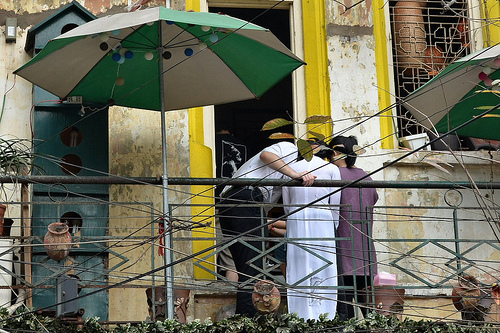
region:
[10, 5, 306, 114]
the green and white umbrella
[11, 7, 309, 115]
the umbrella is green and white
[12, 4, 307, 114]
the opened umbrella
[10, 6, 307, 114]
the umbrella is opened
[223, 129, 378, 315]
the people standing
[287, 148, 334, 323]
the person in a white dress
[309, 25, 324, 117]
the yellow paint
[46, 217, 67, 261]
the pot on the railing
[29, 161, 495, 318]
the metal railing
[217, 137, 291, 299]
the man bending over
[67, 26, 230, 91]
A green and white umbrella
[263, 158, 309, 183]
A persons arm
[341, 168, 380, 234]
A person wearing purple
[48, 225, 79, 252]
A brown pot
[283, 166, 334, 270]
A person wearing a white dress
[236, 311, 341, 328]
Green leaves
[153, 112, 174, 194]
A metal pole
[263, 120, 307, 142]
Brown leaves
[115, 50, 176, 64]
Small balls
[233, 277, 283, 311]
A brown pot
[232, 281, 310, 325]
a pot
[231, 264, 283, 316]
a pot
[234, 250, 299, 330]
a pot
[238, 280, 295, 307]
a pot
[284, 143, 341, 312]
woman dressed in long white dress standing between another woman and a man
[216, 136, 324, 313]
man dressed in black slacks and white shirt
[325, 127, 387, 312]
woman dressed in purple top and black leggings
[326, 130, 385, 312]
woman with her hair in a pony tail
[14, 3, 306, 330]
green and white shade umbrella on the left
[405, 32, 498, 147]
partial green and white shade umbrella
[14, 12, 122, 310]
large green bird house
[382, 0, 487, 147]
large window with wrought iron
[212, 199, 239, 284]
person in grey shorts stading just on the inside of the building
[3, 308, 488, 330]
green ivy type plants growing around the railing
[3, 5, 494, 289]
Old building with chipped paint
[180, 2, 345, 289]
Very high door opening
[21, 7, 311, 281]
White and green umbrella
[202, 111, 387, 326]
Three people standing near an opening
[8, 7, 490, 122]
Two big umbrellas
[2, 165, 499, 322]
Metal balcony railing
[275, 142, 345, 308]
A person wearing a white rob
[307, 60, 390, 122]
White and yellow paint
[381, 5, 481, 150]
Window grill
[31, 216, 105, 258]
Earthen pot on the balcony grill